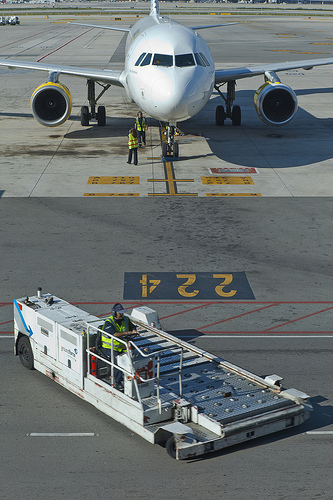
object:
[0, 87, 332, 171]
shadow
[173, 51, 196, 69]
window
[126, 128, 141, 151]
vest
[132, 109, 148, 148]
man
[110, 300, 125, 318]
earmuffs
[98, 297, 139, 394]
man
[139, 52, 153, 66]
window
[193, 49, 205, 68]
window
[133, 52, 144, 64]
window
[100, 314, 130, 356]
vest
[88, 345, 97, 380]
fire extinguisher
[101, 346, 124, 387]
jeans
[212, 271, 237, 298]
numbers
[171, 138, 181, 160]
wheel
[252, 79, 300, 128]
engines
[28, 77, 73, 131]
engines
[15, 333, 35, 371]
tire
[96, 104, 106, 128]
tire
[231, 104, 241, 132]
tire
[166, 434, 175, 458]
tire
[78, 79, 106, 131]
landing gear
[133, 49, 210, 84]
cockpit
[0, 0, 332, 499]
pavement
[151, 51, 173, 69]
window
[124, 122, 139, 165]
person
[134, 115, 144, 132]
vest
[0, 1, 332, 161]
airplane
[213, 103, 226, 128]
wheels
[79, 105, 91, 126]
wheels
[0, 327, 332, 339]
red lines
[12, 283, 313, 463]
heavy machinery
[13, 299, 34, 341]
arrow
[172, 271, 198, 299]
numbers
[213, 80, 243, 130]
landing gear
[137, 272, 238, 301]
224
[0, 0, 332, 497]
airport lot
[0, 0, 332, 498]
ground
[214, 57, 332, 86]
wing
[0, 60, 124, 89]
wing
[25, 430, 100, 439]
line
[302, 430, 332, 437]
line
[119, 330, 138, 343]
steering wheel